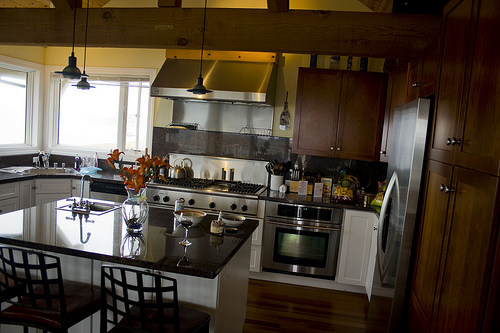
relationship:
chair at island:
[0, 247, 106, 332] [2, 197, 260, 331]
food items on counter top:
[296, 175, 385, 210] [263, 184, 380, 213]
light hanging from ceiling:
[188, 2, 210, 98] [2, 1, 449, 74]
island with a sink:
[2, 197, 260, 331] [65, 198, 120, 217]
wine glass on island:
[176, 210, 208, 247] [2, 197, 260, 331]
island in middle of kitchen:
[2, 197, 260, 331] [1, 0, 497, 332]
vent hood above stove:
[151, 58, 277, 109] [142, 153, 266, 268]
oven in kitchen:
[260, 201, 345, 280] [1, 0, 497, 332]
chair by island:
[95, 264, 211, 333] [2, 197, 260, 331]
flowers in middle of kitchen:
[107, 149, 170, 191] [1, 0, 497, 332]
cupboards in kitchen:
[293, 67, 385, 161] [1, 0, 497, 332]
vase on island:
[122, 184, 149, 233] [2, 197, 260, 331]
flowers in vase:
[107, 149, 170, 191] [122, 184, 149, 233]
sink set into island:
[65, 198, 120, 217] [2, 197, 260, 331]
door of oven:
[261, 219, 338, 279] [260, 201, 345, 280]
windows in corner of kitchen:
[1, 63, 152, 159] [1, 0, 497, 332]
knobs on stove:
[152, 195, 249, 212] [142, 153, 266, 268]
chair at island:
[100, 264, 215, 331] [2, 197, 260, 331]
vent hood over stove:
[151, 58, 277, 109] [142, 153, 266, 268]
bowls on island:
[174, 210, 245, 230] [2, 197, 260, 331]